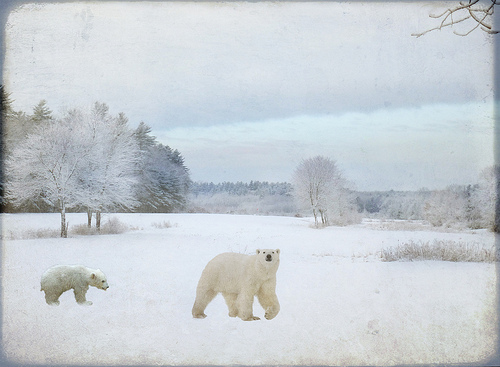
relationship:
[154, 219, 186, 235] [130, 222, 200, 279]
snow on ground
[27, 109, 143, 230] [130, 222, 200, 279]
tree on ground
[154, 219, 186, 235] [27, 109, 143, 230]
snow on tree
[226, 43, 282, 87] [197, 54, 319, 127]
cloud in sky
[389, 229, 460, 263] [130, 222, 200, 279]
grass on ground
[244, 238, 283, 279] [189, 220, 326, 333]
head of bear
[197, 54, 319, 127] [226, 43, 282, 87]
sky with cloud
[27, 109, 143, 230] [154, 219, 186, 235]
tree in snow